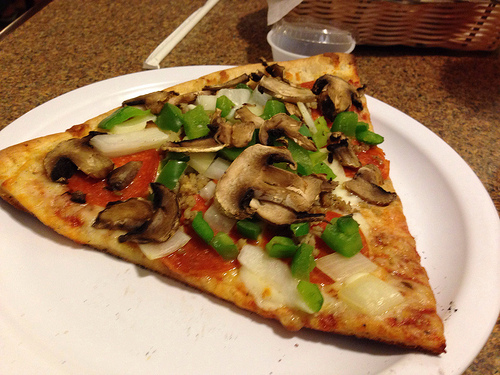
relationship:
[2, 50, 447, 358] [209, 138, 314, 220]
pizza has mushrooms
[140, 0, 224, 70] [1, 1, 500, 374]
straw on table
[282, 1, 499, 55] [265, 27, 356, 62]
basket next to container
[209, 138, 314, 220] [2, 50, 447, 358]
mushrooms on top of pizza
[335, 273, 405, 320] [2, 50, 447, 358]
onion on pizza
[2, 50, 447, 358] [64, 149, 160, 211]
pizza has pepperoni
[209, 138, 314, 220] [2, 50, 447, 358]
mushrooms on pizza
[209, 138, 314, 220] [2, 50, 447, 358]
mushrooms are on pizza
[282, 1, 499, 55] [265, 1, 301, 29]
basket has liner